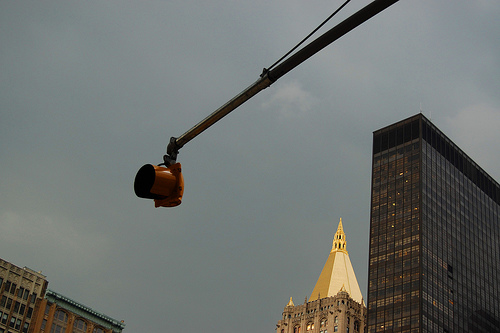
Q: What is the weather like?
A: It is cloudy.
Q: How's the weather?
A: It is cloudy.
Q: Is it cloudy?
A: Yes, it is cloudy.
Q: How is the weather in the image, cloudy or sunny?
A: It is cloudy.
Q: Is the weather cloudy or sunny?
A: It is cloudy.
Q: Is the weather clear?
A: No, it is cloudy.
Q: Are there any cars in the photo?
A: No, there are no cars.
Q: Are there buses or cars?
A: No, there are no cars or buses.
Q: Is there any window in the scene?
A: Yes, there are windows.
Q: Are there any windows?
A: Yes, there are windows.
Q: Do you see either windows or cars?
A: Yes, there are windows.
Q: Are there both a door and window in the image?
A: No, there are windows but no doors.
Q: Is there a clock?
A: No, there are no clocks.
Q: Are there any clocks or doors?
A: No, there are no clocks or doors.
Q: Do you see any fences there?
A: No, there are no fences.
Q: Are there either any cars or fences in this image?
A: No, there are no fences or cars.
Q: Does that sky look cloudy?
A: Yes, the sky is cloudy.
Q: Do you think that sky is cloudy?
A: Yes, the sky is cloudy.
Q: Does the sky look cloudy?
A: Yes, the sky is cloudy.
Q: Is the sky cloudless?
A: No, the sky is cloudy.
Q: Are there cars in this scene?
A: No, there are no cars.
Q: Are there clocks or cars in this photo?
A: No, there are no cars or clocks.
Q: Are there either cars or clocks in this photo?
A: No, there are no cars or clocks.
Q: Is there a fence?
A: No, there are no fences.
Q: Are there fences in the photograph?
A: No, there are no fences.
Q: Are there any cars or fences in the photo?
A: No, there are no fences or cars.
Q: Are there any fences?
A: No, there are no fences.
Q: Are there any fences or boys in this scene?
A: No, there are no fences or boys.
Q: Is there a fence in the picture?
A: No, there are no fences.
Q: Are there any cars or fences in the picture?
A: No, there are no fences or cars.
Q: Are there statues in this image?
A: No, there are no statues.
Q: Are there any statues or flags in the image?
A: No, there are no statues or flags.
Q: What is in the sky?
A: The clouds are in the sky.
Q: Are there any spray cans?
A: No, there are no spray cans.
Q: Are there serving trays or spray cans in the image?
A: No, there are no spray cans or serving trays.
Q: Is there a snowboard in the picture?
A: No, there are no snowboards.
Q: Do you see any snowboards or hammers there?
A: No, there are no snowboards or hammers.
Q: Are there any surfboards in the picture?
A: No, there are no surfboards.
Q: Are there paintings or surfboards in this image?
A: No, there are no surfboards or paintings.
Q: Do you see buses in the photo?
A: No, there are no buses.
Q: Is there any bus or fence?
A: No, there are no buses or fences.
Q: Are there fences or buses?
A: No, there are no buses or fences.